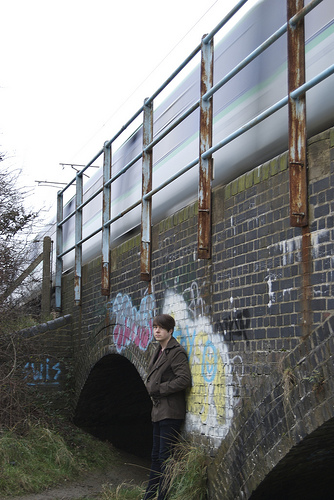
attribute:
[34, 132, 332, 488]
wall — black, brick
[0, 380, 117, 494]
grass — green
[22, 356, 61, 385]
words — light, blue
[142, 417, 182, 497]
pants — black, long, dark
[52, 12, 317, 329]
railing — rusty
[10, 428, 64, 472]
grass — green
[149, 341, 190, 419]
coat — long sleeve, brown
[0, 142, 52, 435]
trees — brown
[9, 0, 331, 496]
bridge — old, cinder block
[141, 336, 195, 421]
coat — brown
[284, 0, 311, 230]
pole — rust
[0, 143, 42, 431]
tree — dead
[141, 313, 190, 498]
boy — young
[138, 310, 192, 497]
man — young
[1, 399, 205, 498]
grass — green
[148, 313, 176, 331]
hair — long